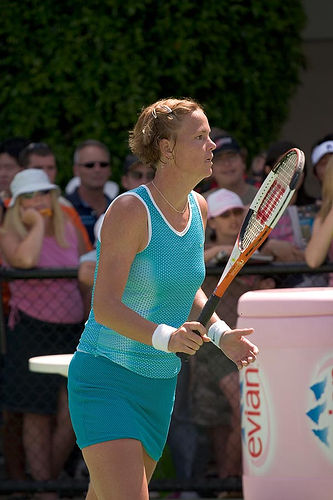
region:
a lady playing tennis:
[66, 93, 297, 499]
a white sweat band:
[150, 322, 177, 358]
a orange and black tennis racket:
[174, 143, 311, 369]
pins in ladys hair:
[149, 103, 170, 121]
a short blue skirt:
[59, 357, 190, 455]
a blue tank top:
[76, 190, 211, 369]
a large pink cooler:
[233, 286, 330, 488]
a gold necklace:
[145, 183, 192, 221]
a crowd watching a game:
[4, 134, 101, 314]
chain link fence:
[15, 285, 78, 343]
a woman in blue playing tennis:
[87, 99, 303, 371]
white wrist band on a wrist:
[148, 322, 177, 354]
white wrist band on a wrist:
[208, 316, 227, 350]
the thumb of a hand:
[230, 326, 256, 337]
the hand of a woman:
[221, 325, 260, 369]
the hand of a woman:
[169, 317, 205, 355]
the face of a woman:
[190, 109, 216, 177]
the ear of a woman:
[155, 137, 176, 160]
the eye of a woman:
[192, 129, 203, 144]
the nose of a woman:
[204, 133, 218, 154]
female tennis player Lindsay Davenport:
[63, 84, 262, 498]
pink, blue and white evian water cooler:
[232, 282, 326, 494]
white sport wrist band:
[148, 320, 175, 349]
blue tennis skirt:
[66, 347, 182, 458]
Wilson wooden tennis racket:
[181, 145, 303, 356]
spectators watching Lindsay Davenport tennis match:
[2, 134, 330, 482]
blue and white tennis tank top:
[71, 184, 204, 375]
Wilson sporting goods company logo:
[254, 177, 284, 219]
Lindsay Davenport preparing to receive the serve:
[10, 86, 328, 496]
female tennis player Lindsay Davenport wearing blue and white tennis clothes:
[59, 98, 215, 498]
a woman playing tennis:
[55, 86, 311, 498]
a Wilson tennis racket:
[208, 144, 307, 342]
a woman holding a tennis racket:
[105, 85, 325, 365]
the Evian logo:
[242, 362, 267, 458]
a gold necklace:
[148, 177, 199, 222]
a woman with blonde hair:
[127, 86, 226, 204]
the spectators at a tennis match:
[3, 134, 158, 257]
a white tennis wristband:
[147, 317, 176, 356]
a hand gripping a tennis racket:
[150, 277, 220, 366]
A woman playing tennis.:
[60, 72, 281, 492]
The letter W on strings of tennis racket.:
[246, 163, 293, 229]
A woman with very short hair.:
[128, 87, 226, 185]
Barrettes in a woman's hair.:
[130, 90, 195, 157]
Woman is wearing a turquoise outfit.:
[62, 97, 219, 477]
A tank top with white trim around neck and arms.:
[81, 173, 212, 379]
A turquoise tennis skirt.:
[54, 350, 180, 457]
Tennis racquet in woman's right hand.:
[169, 132, 306, 362]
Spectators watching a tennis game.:
[5, 100, 328, 261]